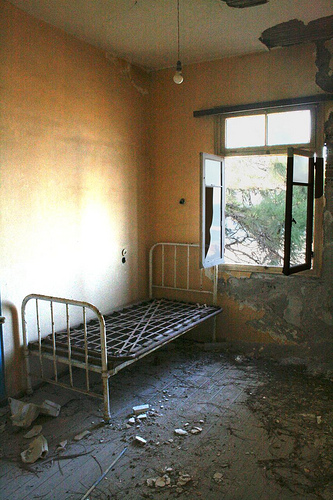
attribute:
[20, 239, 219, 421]
bedframe — white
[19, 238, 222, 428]
bed — rusty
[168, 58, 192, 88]
bulb — white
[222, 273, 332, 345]
broken drywall —  grey 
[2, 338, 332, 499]
surface — grey, wood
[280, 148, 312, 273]
window door — broken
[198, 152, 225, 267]
window door — broken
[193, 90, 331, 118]
curtain rod — black, metal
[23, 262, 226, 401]
bed — rusty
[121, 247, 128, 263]
outlet — electrical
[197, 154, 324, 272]
window — broken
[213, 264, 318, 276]
window sill — white 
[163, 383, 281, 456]
floor. — bottom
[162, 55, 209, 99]
bulb — bare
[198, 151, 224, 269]
wood frame — brown